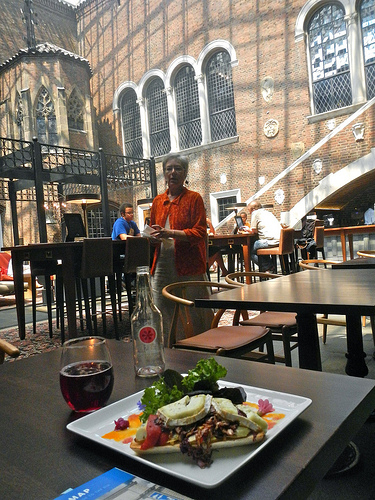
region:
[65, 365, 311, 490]
square white plate with sandwich on it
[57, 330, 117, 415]
dark beverage in a clear glass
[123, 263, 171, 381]
empty clear glass bottle on dark wooden table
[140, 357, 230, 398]
green salad on a square white plate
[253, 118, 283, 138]
round cement decoration on brick wall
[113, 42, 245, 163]
metal mesh over arched windows in brick wall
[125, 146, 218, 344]
short gray haired woman wearing a dark red sweater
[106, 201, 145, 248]
dark haired man wearing short sleeve blue shirt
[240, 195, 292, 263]
bald man with white shirt and blue pants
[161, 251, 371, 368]
dark wood table with two round back chairs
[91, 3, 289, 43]
The wall is made of red brick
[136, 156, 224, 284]
The woman is wearing an orange shirt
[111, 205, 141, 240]
The man has on a blue shirt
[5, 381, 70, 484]
The table is dark wood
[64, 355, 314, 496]
The plate of food on the table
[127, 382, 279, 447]
A sandwich on the plate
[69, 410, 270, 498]
The plate is the color white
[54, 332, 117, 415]
The glass of wine on the table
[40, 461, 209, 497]
A piece of paper on the table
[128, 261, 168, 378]
The empty bottle sitting on the table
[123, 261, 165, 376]
Clear glass bottle on table.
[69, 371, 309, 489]
Food on white plate.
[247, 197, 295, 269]
Man sitting on a chair.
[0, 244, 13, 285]
Orange boot in the background.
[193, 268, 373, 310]
Dark brown wood table.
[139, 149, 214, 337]
Orange sweater on the woman.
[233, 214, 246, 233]
Black monitor in front of the man.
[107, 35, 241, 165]
Windows on the side of the building.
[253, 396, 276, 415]
Pink flower on the plate.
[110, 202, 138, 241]
Man is wearing a blue shirt.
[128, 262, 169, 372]
a bottle on the table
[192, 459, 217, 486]
a white plate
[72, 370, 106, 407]
liquid in a glass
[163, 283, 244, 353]
a chair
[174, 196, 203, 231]
women wearing a red sweater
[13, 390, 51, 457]
a black table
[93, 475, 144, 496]
a book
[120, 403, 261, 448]
food on the plate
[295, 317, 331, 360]
legs on the table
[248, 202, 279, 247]
a person sitting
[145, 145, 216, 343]
This is a person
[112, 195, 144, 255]
This is a person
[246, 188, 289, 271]
This is a person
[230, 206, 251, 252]
This is a person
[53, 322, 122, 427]
This is a glass of wine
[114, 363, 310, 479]
This is a plate of food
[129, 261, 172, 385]
This is an empty bottle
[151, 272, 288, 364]
This is a chair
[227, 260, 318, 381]
This is a chair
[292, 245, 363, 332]
This is a chair